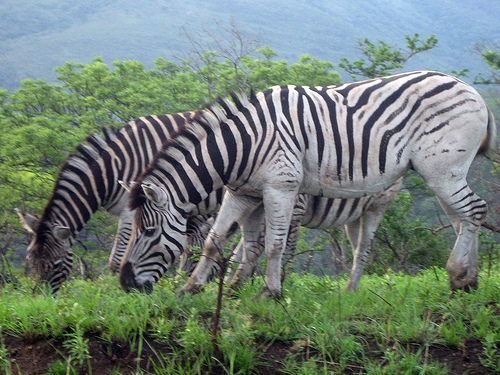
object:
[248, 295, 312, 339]
grass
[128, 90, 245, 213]
mane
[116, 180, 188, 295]
forhead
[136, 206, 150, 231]
forehead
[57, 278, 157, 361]
roots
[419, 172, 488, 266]
leg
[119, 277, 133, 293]
nose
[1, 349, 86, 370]
soil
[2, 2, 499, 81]
mountain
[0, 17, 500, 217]
trees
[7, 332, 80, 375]
dirt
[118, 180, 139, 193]
ears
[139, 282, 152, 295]
mouth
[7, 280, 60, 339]
grass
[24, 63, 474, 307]
zebras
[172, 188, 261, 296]
front leg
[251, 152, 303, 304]
front leg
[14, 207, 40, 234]
ear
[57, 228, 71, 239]
ear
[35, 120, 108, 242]
mane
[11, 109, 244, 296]
zebra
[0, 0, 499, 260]
backdrop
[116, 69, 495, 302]
zebra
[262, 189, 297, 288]
legs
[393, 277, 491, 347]
grass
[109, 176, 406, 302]
zebras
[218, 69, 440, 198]
body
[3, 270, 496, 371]
field